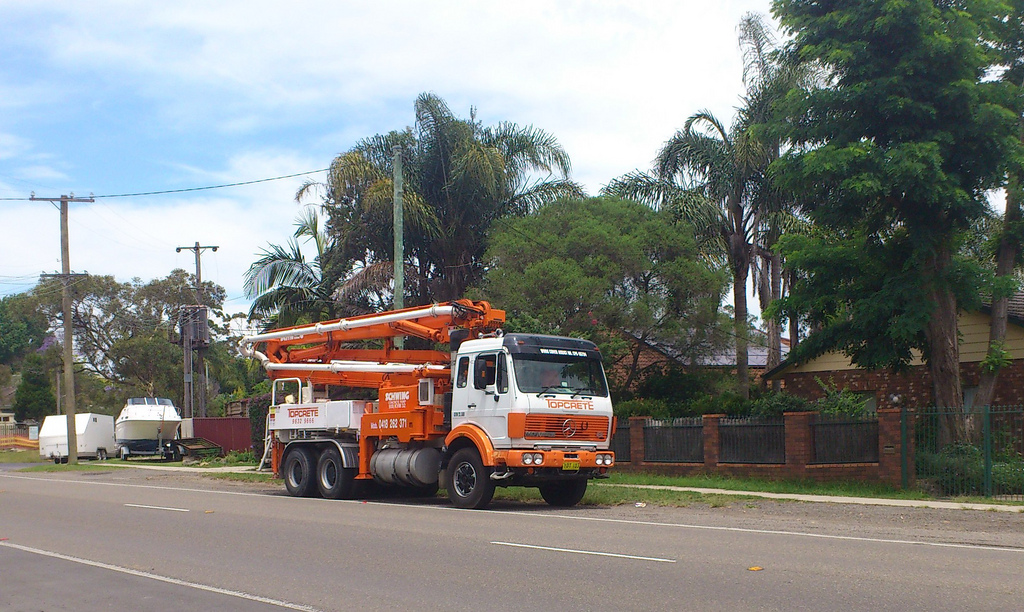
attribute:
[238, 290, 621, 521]
truck — large, orange, white, multicolored, working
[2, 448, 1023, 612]
street — paved, asphalt, grey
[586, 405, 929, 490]
fence — iron, low, brick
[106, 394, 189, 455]
boat — white, large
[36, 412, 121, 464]
trailer — white, parked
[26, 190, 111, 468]
pole — tall, brown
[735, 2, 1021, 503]
tree — large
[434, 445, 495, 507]
tire — rubber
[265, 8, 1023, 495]
trees — green, different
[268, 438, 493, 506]
tires — black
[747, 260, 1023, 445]
house — yellow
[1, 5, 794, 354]
sky — blue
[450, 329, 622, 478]
cab — white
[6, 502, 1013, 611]
lines — white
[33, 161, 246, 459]
poles — multiple